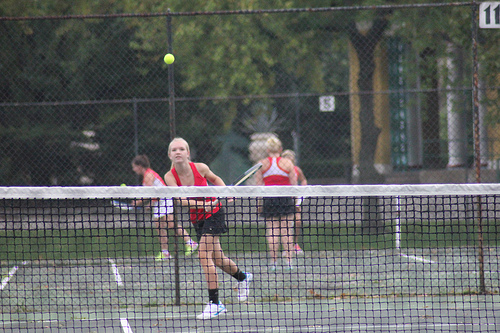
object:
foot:
[195, 300, 224, 320]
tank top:
[262, 157, 291, 187]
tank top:
[172, 163, 222, 224]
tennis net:
[0, 186, 499, 333]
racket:
[205, 162, 264, 212]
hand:
[204, 201, 216, 213]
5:
[319, 94, 335, 112]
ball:
[163, 53, 175, 65]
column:
[445, 44, 466, 167]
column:
[476, 54, 490, 167]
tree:
[128, 0, 411, 184]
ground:
[336, 216, 499, 248]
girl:
[162, 136, 252, 320]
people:
[282, 149, 308, 255]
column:
[405, 38, 423, 169]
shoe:
[196, 301, 227, 320]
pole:
[108, 254, 123, 286]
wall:
[301, 170, 499, 217]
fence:
[0, 184, 500, 331]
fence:
[0, 3, 500, 226]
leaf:
[266, 57, 276, 65]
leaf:
[242, 55, 253, 64]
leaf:
[190, 23, 200, 32]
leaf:
[143, 43, 154, 49]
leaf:
[144, 23, 160, 33]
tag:
[320, 95, 335, 112]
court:
[0, 246, 499, 331]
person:
[250, 136, 308, 268]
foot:
[234, 271, 252, 302]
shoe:
[237, 271, 253, 301]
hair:
[264, 135, 282, 153]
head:
[168, 137, 190, 163]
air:
[12, 10, 132, 98]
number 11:
[479, 3, 499, 28]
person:
[129, 154, 199, 262]